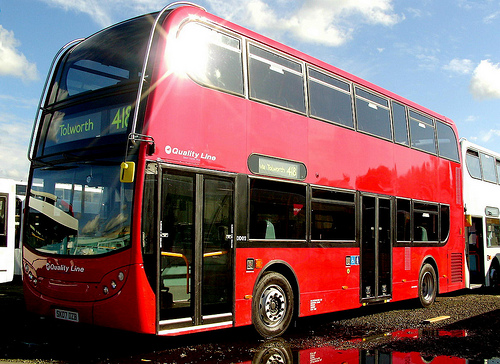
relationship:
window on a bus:
[434, 117, 461, 162] [19, 0, 465, 338]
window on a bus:
[248, 176, 305, 238] [19, 0, 465, 338]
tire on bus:
[247, 273, 305, 344] [19, 0, 465, 338]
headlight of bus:
[21, 267, 33, 294] [17, 9, 470, 306]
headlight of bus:
[105, 265, 127, 295] [17, 9, 470, 306]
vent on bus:
[449, 252, 461, 281] [19, 0, 465, 338]